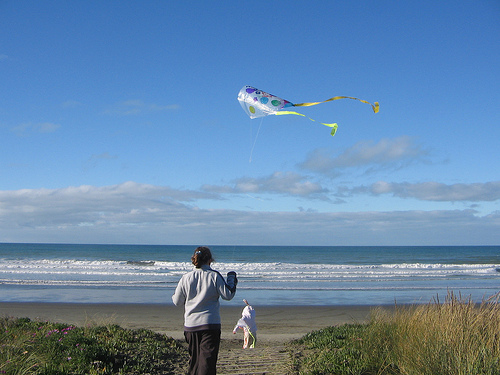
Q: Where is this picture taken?
A: On a beach.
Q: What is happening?
A: Flying a kite.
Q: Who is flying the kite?
A: A woman.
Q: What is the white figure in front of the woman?
A: Dog.